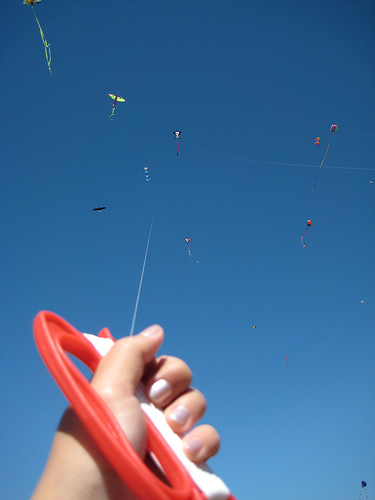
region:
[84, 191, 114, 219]
colorful kite in air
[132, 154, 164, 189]
colorful kite in air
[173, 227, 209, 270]
colorful kite in air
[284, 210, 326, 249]
colorful kite in air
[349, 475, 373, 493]
colorful kite in air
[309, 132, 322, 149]
colorful kite in air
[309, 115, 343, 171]
colorful kite in air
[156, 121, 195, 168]
colorful kite in air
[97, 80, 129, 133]
colorful kite in air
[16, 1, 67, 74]
colorful kite in air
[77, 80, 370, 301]
a group of objects in air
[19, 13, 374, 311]
group of kites flying in air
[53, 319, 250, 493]
hand of the person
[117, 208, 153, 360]
a white thread of kite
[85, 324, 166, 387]
thumb finger of the boy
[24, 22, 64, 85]
tail of the kite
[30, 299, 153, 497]
a red holder by boy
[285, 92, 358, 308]
a kites in air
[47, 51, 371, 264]
several kites in the sky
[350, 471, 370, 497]
purple kite in the sky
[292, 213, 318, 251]
rainbow kite in the sky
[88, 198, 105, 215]
bird flying in the sky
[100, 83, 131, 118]
yellow and green kite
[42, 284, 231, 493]
person holding a kite string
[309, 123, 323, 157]
rainbow kite in the sky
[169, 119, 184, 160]
black and white kite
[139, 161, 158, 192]
blue kite in the sky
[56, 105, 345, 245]
Blue sky filled with kites.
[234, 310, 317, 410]
Bright blue sky high above.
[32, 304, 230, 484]
Hand holding onto a kite.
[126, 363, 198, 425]
Silver polish on the nails.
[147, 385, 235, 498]
White kite string around the red handle.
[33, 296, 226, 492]
Red handle wrapped with white string.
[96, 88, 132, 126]
A bright yellow kite high in the sky.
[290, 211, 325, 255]
Red kite high in the sky.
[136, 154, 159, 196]
Multi colored kite in the sky.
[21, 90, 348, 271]
Ten kites high in the sky.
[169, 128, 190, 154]
kite in the sky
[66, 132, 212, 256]
kites in the sky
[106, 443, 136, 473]
the handle is red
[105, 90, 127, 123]
a kite with a yellow swirly tail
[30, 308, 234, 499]
a red kite handle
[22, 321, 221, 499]
a hand holding something red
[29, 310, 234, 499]
a red kite handle with white string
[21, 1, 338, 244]
a bunch of kites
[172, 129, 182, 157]
a black and white kite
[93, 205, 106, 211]
a black bird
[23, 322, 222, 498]
a hand with painted nails